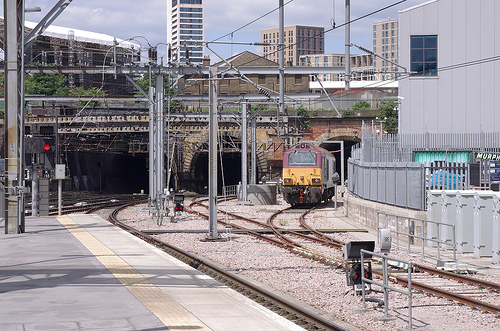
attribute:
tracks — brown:
[117, 185, 500, 329]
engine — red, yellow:
[282, 141, 340, 207]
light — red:
[41, 142, 52, 153]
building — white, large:
[165, 2, 208, 66]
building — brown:
[263, 24, 325, 73]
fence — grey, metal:
[348, 153, 428, 211]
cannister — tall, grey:
[54, 162, 68, 205]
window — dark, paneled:
[409, 32, 442, 79]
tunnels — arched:
[25, 102, 402, 178]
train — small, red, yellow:
[283, 139, 338, 205]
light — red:
[44, 141, 53, 153]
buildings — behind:
[165, 4, 404, 79]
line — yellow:
[56, 212, 217, 328]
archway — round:
[183, 129, 273, 187]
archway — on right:
[309, 132, 368, 187]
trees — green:
[1, 72, 100, 98]